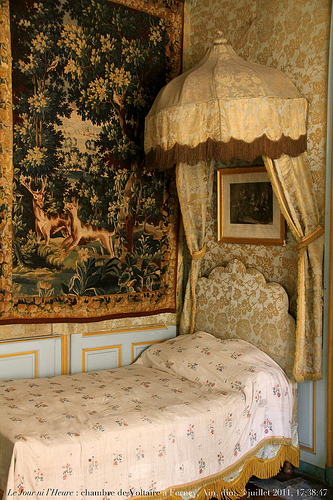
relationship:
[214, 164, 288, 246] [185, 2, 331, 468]
photo on wall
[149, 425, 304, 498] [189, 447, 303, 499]
bed skirt has fringe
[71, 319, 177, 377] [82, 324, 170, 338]
wall has edge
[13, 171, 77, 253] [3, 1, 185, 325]
buck on tapestry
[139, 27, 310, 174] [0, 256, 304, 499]
feature above bed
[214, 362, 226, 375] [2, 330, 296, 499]
flower on bed spread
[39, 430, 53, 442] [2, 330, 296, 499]
flower on bed spread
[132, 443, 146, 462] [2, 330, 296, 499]
flower on bed spread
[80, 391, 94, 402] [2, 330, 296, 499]
flower on bed spread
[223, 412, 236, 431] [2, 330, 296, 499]
flower on bed spread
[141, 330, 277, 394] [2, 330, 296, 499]
pillow under bed spread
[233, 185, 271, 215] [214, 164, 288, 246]
people are in photo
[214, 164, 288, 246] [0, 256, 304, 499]
photo above bed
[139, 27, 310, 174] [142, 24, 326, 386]
feature on top of canopy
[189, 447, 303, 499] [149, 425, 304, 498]
fringe on bed skirt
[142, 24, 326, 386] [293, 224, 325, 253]
canopy has tie back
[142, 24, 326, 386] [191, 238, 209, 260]
canopy has tie back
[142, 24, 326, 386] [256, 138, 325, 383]
canopy has curtain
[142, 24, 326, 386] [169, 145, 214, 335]
canopy has curtain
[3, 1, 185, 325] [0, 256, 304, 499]
tapestry next to bed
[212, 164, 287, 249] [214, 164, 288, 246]
frame surrounds photo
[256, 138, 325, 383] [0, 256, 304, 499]
curtain next to bed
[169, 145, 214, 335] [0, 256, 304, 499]
curtain next to bed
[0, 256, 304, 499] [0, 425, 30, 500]
bed has foot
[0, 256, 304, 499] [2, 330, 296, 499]
bed has bed spread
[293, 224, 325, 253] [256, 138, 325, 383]
tie back for curtain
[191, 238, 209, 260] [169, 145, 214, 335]
tie back for curtain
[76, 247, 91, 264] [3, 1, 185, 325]
flower on tapestry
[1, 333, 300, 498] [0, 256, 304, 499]
bed cover covering bed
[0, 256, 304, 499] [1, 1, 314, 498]
bed setup in bedroom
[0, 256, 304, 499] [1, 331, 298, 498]
bed standing in bedroom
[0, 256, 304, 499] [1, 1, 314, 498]
bed mounted in in bedroom